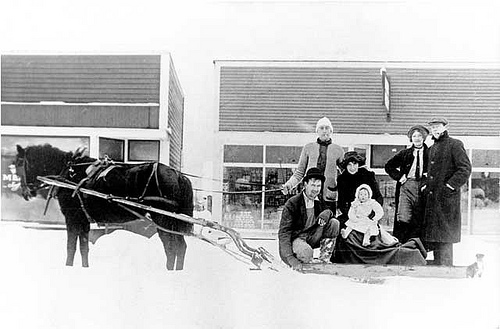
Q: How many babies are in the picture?
A: One.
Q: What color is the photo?
A: Black and white.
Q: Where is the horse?
A: In front of the sleigh.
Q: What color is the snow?
A: White.